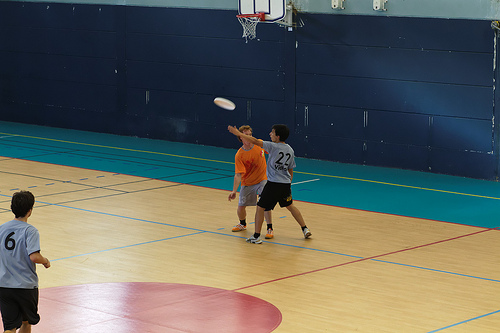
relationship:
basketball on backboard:
[235, 12, 264, 42] [237, 0, 286, 23]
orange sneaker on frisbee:
[230, 225, 245, 231] [213, 95, 235, 110]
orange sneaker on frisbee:
[264, 228, 274, 238] [213, 95, 235, 110]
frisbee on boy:
[214, 97, 236, 111] [229, 125, 276, 239]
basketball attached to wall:
[235, 12, 264, 42] [223, 50, 364, 95]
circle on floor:
[1, 282, 283, 333] [266, 287, 418, 328]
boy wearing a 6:
[222, 118, 319, 249] [4, 231, 16, 251]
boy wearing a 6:
[222, 121, 277, 242] [4, 231, 16, 251]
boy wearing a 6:
[1, 188, 53, 330] [4, 231, 16, 251]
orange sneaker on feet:
[230, 225, 245, 231] [221, 221, 279, 242]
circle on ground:
[1, 282, 283, 333] [161, 248, 277, 329]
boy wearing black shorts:
[229, 125, 276, 239] [257, 181, 297, 212]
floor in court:
[4, 144, 487, 331] [0, 0, 499, 333]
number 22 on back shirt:
[273, 150, 291, 170] [258, 138, 294, 183]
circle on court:
[1, 282, 281, 331] [1, 114, 497, 331]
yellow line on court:
[6, 128, 498, 206] [24, 107, 413, 331]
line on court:
[315, 233, 403, 287] [1, 114, 497, 331]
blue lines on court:
[2, 174, 498, 331] [1, 114, 497, 331]